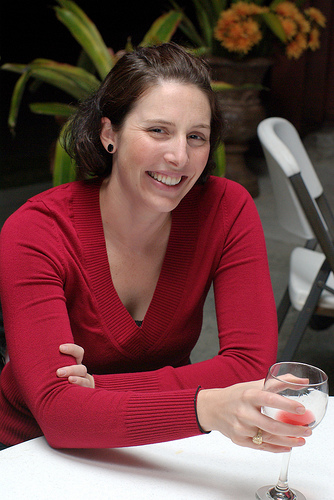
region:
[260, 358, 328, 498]
A glass with a tiny bit of wine in it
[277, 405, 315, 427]
Red wine in a wine glass.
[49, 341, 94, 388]
Three white fingers on a woman's left hand.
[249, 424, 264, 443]
Gold ring on a woman's hand holding a wine glass.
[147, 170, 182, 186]
White teeth on a smiling woman holding a wine glass.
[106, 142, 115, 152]
Round black earring on a woman who is smiling.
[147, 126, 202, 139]
Dark eyes on a woman who is smiling.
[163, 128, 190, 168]
Nose on a woman's face who is smiling.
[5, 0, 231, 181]
Long green leaves on a plant behind a woman's head.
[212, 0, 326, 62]
Orange flowers in a large planter to the back right of a woman's head.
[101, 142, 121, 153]
earring is black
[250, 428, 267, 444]
women is wearing a ring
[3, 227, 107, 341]
women is wearing a red sweater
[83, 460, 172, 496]
table is white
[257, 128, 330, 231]
a white chair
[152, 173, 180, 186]
the womens teeth are white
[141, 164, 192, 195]
a smile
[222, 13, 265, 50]
flowers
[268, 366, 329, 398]
a wine glass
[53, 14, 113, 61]
a green plant leaf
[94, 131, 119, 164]
black gauges in ears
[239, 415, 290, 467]
gold wedding ring on hand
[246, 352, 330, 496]
wine glass with small amount of wine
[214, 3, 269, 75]
yellow flowers in a pot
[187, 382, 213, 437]
small black bracelet on wrist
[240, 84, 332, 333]
white folding chair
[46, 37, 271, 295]
woman with no make up on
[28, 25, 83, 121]
green long leafed plant in a pot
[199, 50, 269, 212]
large pot for plants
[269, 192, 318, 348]
folding chair with white seating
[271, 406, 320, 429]
wine in the glass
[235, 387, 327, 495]
wine glass in hand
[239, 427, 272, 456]
gold ring on finger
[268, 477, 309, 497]
base of wine glass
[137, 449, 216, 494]
shadow on the table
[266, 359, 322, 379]
rim of the glass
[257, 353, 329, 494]
glass on the table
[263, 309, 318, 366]
leg of the chair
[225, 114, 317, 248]
back of the chair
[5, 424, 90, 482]
elbow on the table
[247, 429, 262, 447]
women is wearing a ring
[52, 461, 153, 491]
a white table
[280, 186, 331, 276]
the chair is white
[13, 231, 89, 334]
women wearing a red sweater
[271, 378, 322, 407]
a wine glass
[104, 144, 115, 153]
the earring is black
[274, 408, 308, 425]
red liquid in the glass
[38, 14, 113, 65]
a plant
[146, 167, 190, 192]
the women is smiling